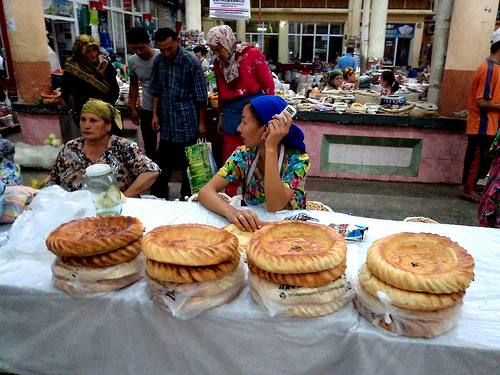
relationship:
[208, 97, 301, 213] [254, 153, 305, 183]
woman wearing scarf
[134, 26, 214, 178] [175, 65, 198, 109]
man carrying bag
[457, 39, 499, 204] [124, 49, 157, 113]
man wearing t-shirt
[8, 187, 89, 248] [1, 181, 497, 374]
bag on table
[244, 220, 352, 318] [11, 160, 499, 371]
bread on table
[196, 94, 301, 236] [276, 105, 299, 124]
woman has cell phone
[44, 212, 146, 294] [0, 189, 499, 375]
bread on table cloth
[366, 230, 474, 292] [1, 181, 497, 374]
bread product on table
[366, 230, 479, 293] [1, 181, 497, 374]
bread product on table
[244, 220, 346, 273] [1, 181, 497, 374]
bread on table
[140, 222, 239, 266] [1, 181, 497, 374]
bread on table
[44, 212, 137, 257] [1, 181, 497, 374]
bread on table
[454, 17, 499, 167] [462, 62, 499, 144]
man wearing a shirt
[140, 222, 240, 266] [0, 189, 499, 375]
bread on table cloth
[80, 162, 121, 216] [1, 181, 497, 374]
jar on table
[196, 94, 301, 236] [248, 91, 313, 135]
woman with scarf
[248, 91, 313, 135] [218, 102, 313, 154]
scarf on head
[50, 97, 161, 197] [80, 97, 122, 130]
woman with scarf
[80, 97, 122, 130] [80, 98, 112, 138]
scarf on head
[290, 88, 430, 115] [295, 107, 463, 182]
food on table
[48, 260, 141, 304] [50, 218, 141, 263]
wrapper around bread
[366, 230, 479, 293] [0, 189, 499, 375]
bread product on a table cloth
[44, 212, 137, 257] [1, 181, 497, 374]
bread on a table